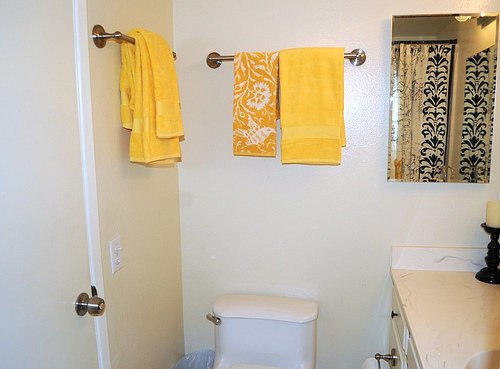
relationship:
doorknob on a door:
[72, 287, 108, 322] [0, 0, 107, 367]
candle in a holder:
[486, 201, 499, 229] [472, 223, 499, 283]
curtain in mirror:
[391, 41, 456, 183] [389, 14, 499, 184]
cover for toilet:
[213, 287, 320, 324] [205, 292, 321, 369]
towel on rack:
[278, 46, 345, 164] [203, 45, 370, 68]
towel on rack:
[226, 50, 277, 163] [203, 45, 370, 68]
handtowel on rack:
[119, 27, 185, 164] [88, 22, 180, 59]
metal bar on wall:
[206, 47, 366, 67] [171, 5, 498, 367]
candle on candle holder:
[483, 201, 498, 228] [475, 220, 497, 285]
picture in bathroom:
[13, 14, 499, 367] [5, 2, 499, 367]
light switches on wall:
[109, 236, 123, 275] [90, 1, 182, 366]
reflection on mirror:
[391, 16, 496, 180] [386, 10, 492, 184]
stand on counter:
[474, 223, 497, 284] [394, 268, 499, 368]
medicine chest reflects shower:
[384, 12, 498, 187] [389, 18, 498, 198]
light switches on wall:
[109, 236, 123, 275] [77, 3, 221, 363]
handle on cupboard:
[376, 344, 396, 364] [369, 9, 458, 185]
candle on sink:
[486, 201, 499, 229] [392, 238, 485, 364]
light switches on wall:
[106, 235, 126, 275] [88, 167, 150, 210]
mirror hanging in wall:
[386, 10, 492, 184] [185, 5, 399, 296]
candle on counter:
[486, 201, 499, 229] [388, 266, 485, 366]